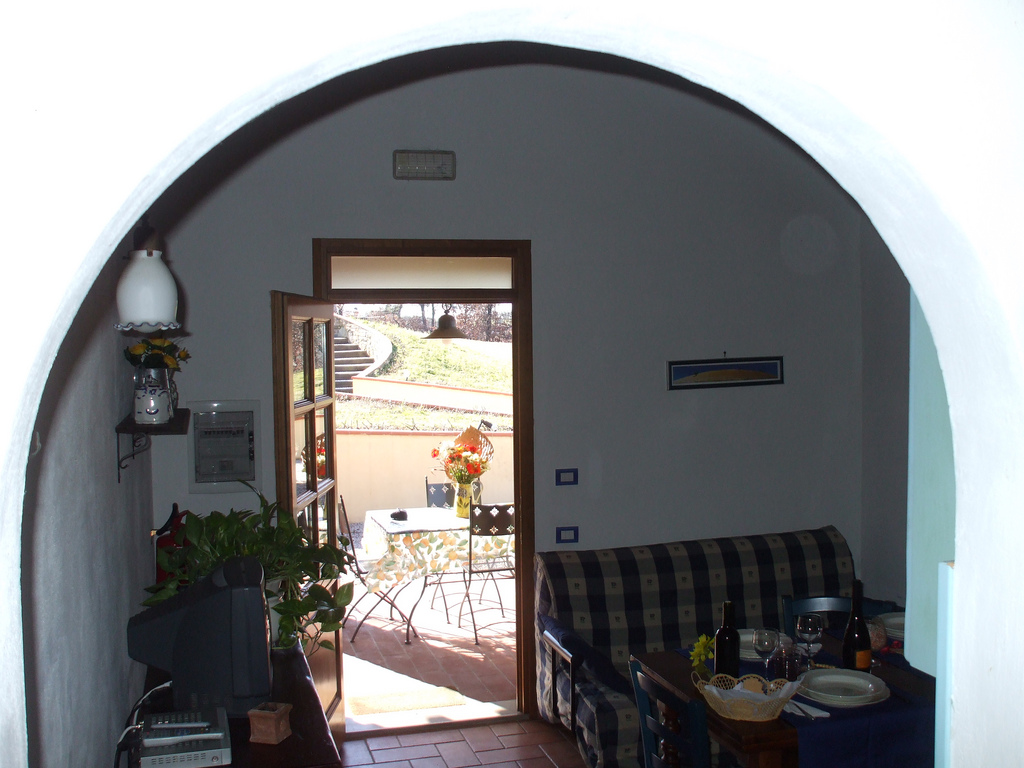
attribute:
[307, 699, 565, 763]
bricks — red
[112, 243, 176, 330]
light — white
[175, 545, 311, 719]
television — black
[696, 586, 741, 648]
bottle — black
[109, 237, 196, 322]
shade — white